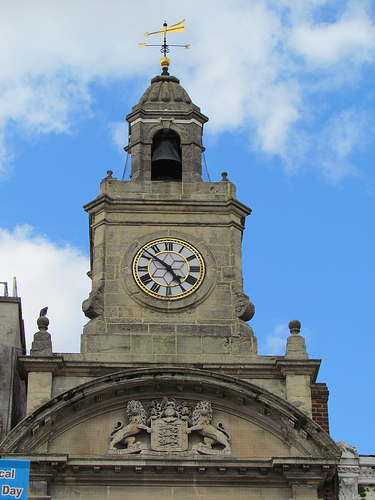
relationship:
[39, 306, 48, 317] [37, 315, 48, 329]
bird perch top stone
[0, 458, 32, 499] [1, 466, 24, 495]
blue sign says cal day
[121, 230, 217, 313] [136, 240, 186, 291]
clock says 4:53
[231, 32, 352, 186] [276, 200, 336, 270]
clouds in sky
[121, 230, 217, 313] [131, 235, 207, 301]
clock has golden trim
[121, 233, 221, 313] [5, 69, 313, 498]
clock on tower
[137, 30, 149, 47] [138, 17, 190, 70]
arrow heads on windmill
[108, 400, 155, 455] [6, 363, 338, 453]
carvings on structure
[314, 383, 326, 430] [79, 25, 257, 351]
brick on tower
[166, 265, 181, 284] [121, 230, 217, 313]
hand on clock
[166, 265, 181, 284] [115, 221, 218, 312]
hand on clock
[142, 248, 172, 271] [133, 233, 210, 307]
hand of clock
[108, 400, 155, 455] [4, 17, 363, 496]
carvings on building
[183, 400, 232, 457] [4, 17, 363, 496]
carvings on building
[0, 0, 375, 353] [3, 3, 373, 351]
clouds in sky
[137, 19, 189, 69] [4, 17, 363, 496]
wind meter on top of building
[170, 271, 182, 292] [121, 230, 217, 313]
hand of clock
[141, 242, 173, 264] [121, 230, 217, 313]
hand of clock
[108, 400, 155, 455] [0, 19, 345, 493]
carvings carvings in architecture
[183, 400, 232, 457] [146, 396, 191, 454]
carvings between tablet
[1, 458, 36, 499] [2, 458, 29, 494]
corner of sign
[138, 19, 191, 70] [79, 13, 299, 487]
wind meter on top of tower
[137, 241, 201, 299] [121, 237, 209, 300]
numbers on clock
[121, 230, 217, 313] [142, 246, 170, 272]
clock has minute hand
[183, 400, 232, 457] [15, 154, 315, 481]
carvings on building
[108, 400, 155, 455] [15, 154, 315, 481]
carvings on building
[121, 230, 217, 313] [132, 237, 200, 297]
clock has face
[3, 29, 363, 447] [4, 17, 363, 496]
sky over building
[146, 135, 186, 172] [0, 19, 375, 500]
bell in architecture